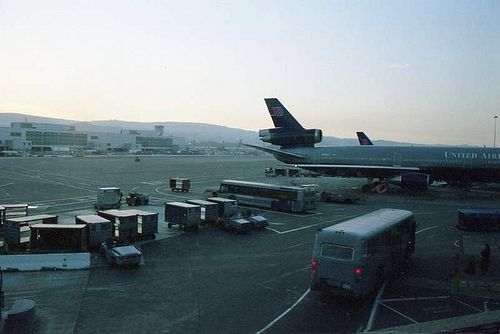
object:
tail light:
[308, 259, 316, 266]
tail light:
[309, 268, 318, 274]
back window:
[320, 243, 339, 260]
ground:
[0, 153, 499, 333]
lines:
[363, 279, 388, 331]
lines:
[276, 212, 360, 236]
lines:
[152, 177, 226, 200]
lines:
[256, 286, 311, 333]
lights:
[354, 267, 360, 274]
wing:
[278, 161, 425, 177]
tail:
[256, 97, 321, 151]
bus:
[214, 179, 322, 217]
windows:
[218, 184, 226, 192]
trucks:
[216, 204, 254, 233]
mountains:
[0, 111, 423, 156]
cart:
[166, 176, 189, 193]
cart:
[163, 200, 203, 230]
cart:
[183, 197, 222, 227]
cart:
[93, 186, 125, 212]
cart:
[25, 222, 87, 255]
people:
[478, 241, 492, 264]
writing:
[440, 150, 499, 161]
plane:
[235, 97, 500, 195]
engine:
[382, 173, 433, 192]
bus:
[308, 206, 416, 310]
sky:
[0, 0, 499, 148]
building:
[0, 121, 90, 155]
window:
[333, 246, 355, 263]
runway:
[0, 156, 499, 333]